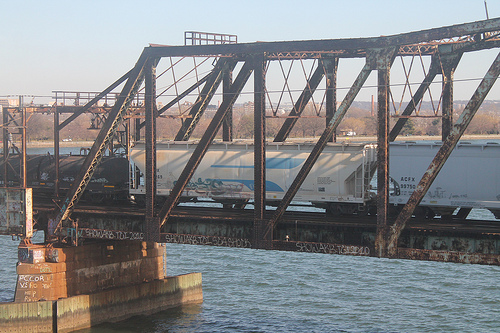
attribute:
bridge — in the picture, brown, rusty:
[1, 15, 498, 331]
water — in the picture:
[0, 232, 500, 330]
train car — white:
[388, 118, 498, 225]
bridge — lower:
[31, 62, 498, 264]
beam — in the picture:
[387, 51, 498, 252]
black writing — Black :
[397, 172, 417, 193]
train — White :
[126, 140, 378, 212]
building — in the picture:
[59, 135, 76, 142]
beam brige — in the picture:
[146, 41, 271, 236]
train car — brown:
[2, 144, 146, 201]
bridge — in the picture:
[190, 6, 437, 272]